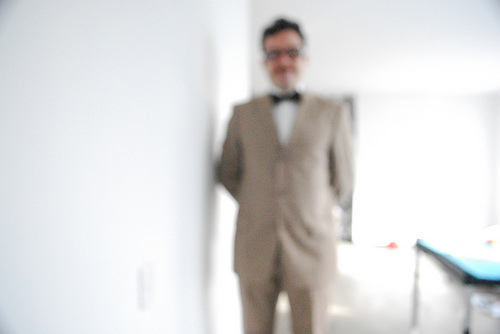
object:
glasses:
[265, 49, 300, 59]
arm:
[330, 105, 356, 209]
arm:
[218, 111, 243, 201]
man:
[213, 19, 358, 334]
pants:
[239, 283, 329, 333]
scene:
[0, 0, 499, 334]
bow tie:
[267, 91, 301, 105]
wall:
[1, 0, 500, 332]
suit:
[217, 90, 358, 334]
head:
[262, 18, 309, 94]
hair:
[262, 16, 302, 39]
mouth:
[274, 71, 293, 79]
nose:
[278, 53, 293, 66]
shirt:
[271, 96, 302, 143]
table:
[411, 239, 493, 321]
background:
[23, 2, 499, 259]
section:
[0, 0, 499, 334]